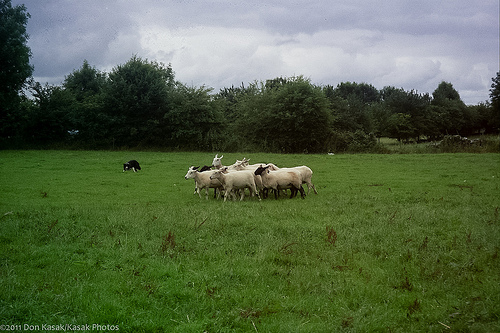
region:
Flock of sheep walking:
[183, 153, 320, 205]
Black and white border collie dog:
[118, 155, 144, 173]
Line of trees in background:
[8, 64, 496, 157]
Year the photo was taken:
[6, 322, 21, 331]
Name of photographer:
[21, 321, 67, 330]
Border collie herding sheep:
[120, 156, 145, 173]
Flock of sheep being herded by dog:
[183, 153, 319, 203]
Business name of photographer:
[63, 320, 120, 330]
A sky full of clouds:
[38, 7, 494, 76]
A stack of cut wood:
[428, 132, 493, 154]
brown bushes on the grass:
[148, 229, 185, 253]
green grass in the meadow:
[172, 223, 336, 294]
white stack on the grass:
[323, 144, 335, 159]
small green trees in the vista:
[370, 102, 440, 143]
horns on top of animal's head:
[207, 151, 235, 161]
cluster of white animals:
[182, 149, 327, 205]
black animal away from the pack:
[114, 155, 147, 178]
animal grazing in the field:
[114, 160, 158, 184]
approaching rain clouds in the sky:
[60, 43, 131, 68]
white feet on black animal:
[132, 165, 145, 171]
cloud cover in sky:
[17, 3, 499, 93]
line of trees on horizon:
[48, 57, 498, 150]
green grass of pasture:
[1, 152, 497, 327]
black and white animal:
[120, 157, 140, 174]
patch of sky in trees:
[62, 125, 84, 142]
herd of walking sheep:
[183, 150, 315, 201]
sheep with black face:
[252, 162, 299, 187]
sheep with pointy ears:
[210, 151, 223, 167]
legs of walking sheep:
[191, 182, 316, 198]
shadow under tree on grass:
[389, 133, 444, 147]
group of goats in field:
[188, 147, 328, 203]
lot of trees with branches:
[88, 63, 420, 146]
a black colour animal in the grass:
[113, 150, 145, 179]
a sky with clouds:
[91, 10, 392, 51]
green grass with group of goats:
[103, 138, 461, 305]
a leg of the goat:
[308, 175, 318, 196]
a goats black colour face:
[253, 162, 268, 174]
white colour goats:
[190, 168, 256, 192]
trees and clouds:
[106, 38, 448, 138]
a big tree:
[0, 8, 38, 161]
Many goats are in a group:
[182, 151, 320, 200]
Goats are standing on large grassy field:
[1, 148, 499, 328]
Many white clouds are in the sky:
[6, 0, 495, 107]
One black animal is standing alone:
[119, 156, 143, 176]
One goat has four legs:
[209, 164, 263, 203]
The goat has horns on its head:
[182, 163, 201, 180]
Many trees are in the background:
[1, 61, 497, 152]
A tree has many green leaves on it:
[253, 83, 333, 151]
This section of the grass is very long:
[1, 210, 499, 326]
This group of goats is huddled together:
[182, 152, 322, 202]